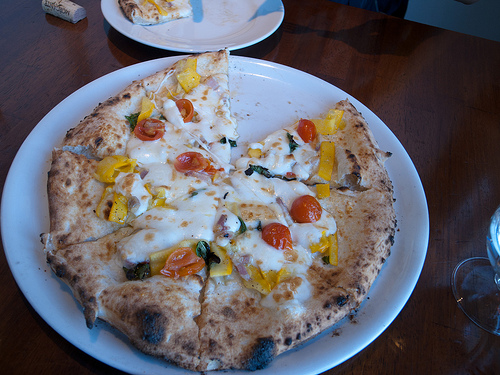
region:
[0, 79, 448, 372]
pizza dinner on a plate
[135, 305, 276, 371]
burnt areas of pizza crust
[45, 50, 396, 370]
pizza with a slice taken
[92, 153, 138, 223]
yellow peppers on a pizza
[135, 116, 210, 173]
tomatoes on a pizza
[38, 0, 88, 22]
cork from a bottle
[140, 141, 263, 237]
cheese topping on a pizza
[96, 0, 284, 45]
pizza served on a plate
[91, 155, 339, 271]
pizza toppings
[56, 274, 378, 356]
pizza crust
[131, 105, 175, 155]
red tomatoes on melted cheese topping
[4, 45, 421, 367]
pizza missing slice on white plate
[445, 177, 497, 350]
stemmed clear glass sitting on table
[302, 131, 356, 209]
yellow peppers on melted cheese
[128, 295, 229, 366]
burnt spots on crust of pizza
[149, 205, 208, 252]
white melted mozzarella cheese on pizza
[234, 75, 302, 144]
crumbs on white ceramic plate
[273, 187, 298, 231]
slices of red onion on pizza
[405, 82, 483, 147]
dark stained shiny wood table top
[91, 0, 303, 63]
white ceramic plate with slice of pizza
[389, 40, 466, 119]
A dark brown table.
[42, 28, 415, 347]
A very tasty pizza.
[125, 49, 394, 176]
Pizza with one slice missing.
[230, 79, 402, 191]
Pizza on a white plate.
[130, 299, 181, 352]
Piece of burnt crust.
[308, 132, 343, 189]
Yellow peppers used as a topping.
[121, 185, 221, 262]
Piece of pizza with extra cheese.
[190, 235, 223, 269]
Spinach on the pizza for added flavor.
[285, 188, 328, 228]
Red tomatoes on the pizza.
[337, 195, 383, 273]
No toppings on this part of the slice.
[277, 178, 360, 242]
red cherry tomato cut in half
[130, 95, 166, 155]
red cherry tomato cut in half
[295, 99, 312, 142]
red cherry tomato cut in half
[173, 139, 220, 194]
red cherry tomato cut in half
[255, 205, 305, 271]
red cherry tomato cut in half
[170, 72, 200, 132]
red cherry tomato cut in half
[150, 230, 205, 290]
red cherry tomato cut in half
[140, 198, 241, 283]
melted cheese on top of pizza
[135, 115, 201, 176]
melted cheese on top of pizza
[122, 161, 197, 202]
melted cheese on top of pizza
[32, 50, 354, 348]
small pizza on white plate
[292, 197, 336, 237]
small red tomatoes on pizza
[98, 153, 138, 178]
yellow peppers on pizza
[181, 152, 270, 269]
melted cheese atop pizza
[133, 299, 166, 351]
golden crust on pizza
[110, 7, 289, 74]
small white plate in background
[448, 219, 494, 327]
clear wine glass on right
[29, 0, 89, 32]
small wine cork on table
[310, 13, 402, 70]
shadow of wine glass on table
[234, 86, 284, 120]
small crumbs from missing slice in plate